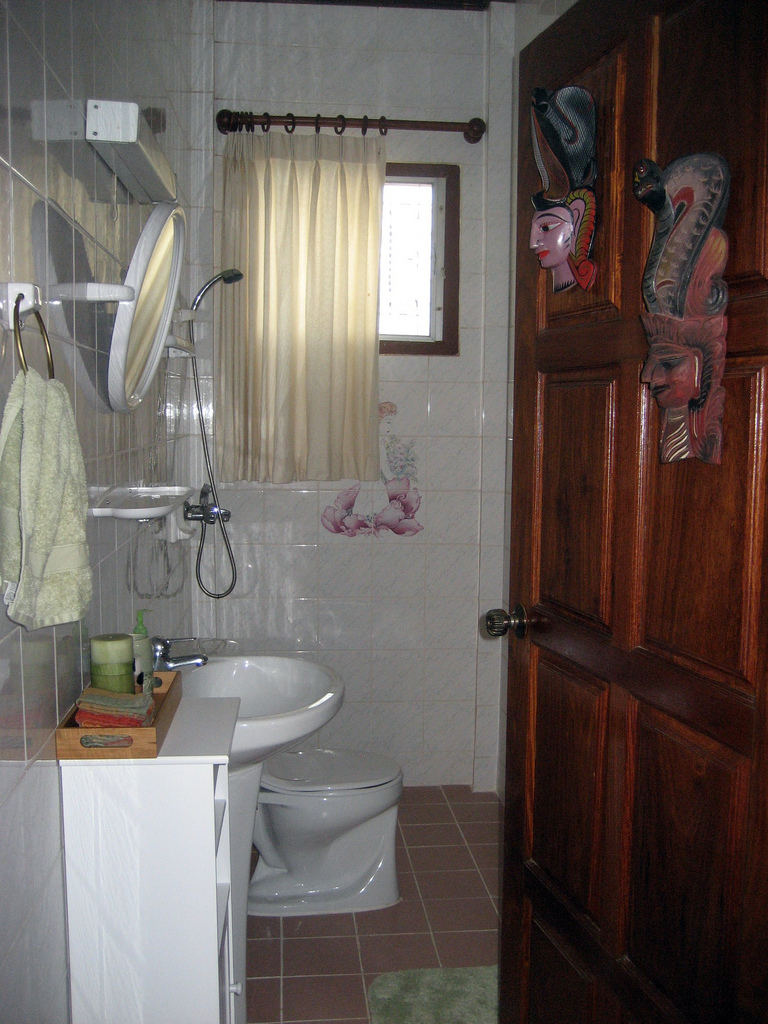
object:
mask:
[632, 151, 732, 463]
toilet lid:
[261, 748, 402, 794]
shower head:
[184, 268, 244, 600]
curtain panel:
[211, 129, 384, 483]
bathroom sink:
[171, 655, 345, 772]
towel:
[0, 362, 92, 633]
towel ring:
[13, 291, 56, 379]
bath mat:
[364, 961, 499, 1022]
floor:
[248, 780, 501, 1024]